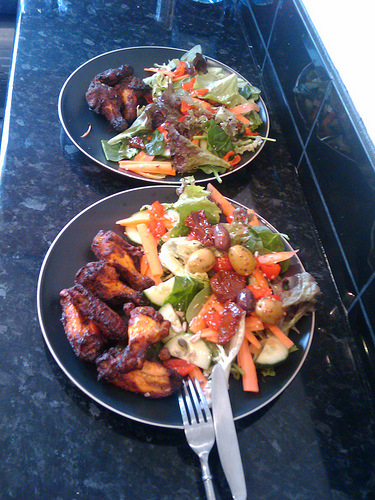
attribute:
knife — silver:
[208, 362, 247, 499]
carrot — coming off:
[207, 181, 239, 223]